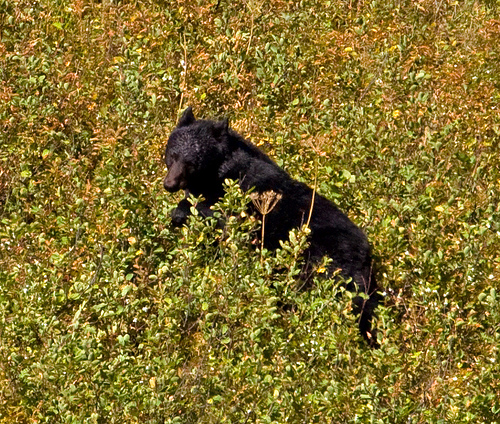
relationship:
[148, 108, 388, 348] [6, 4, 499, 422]
bear in grass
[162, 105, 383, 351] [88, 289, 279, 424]
bear in a field of grass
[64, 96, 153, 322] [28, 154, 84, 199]
these plants are tall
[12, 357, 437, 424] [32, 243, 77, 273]
plants are yellow and green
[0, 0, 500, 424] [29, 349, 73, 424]
leaves are light green and brown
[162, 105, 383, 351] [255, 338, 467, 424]
bear in brush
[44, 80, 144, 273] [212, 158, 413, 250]
plant in front of bear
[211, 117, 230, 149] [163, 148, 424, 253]
left ear of bear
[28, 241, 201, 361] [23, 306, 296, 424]
leaves in field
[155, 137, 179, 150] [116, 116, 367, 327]
eye of bear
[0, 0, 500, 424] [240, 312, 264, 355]
leaves are tall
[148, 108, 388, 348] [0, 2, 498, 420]
bear in underbrush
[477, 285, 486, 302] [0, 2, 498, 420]
leaf in underbrush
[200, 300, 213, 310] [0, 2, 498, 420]
leaf in underbrush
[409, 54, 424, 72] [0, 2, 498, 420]
leaf in underbrush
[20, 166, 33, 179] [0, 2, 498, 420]
leaf in underbrush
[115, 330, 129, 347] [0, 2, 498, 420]
leaf in underbrush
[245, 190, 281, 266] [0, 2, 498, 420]
twig in underbrush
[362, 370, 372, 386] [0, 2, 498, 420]
leaf in underbrush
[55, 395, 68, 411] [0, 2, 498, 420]
leaf in underbrush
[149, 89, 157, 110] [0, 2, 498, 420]
leaf in underbrush